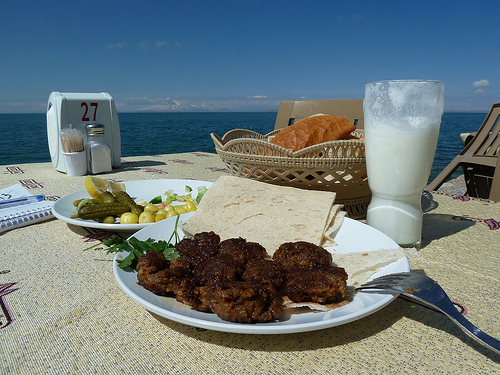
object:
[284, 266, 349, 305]
food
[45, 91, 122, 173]
holder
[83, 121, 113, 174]
salt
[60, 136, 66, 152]
toothpicks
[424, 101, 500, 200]
chair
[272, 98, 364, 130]
chair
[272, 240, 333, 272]
meat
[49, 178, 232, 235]
plate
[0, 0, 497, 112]
sky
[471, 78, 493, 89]
cloud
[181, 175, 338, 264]
bread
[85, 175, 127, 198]
lemon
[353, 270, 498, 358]
fork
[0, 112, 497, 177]
water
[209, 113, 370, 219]
basket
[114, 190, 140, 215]
pickle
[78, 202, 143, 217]
pickle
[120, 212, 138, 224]
bean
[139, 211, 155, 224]
bean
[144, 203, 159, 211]
bean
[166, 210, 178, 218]
bean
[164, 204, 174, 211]
bean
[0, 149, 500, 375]
tablecloth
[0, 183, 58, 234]
notebook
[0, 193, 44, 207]
pen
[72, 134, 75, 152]
toothpicks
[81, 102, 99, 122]
number "27"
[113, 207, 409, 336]
plate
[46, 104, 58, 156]
napkins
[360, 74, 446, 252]
glass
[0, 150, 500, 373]
table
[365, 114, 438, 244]
liquid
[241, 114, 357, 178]
bread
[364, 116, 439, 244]
drink